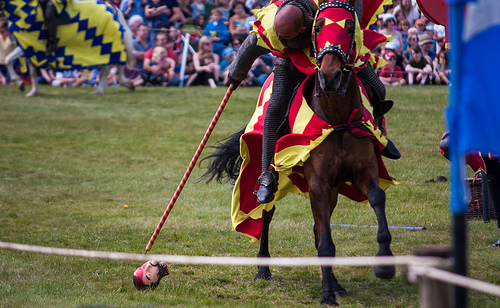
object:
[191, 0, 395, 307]
horse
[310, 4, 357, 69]
mask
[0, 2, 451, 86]
people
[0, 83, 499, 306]
grass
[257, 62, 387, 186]
legging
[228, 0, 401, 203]
man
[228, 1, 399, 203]
armor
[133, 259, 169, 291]
head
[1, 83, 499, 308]
ground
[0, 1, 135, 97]
horse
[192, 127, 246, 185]
tail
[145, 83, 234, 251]
pole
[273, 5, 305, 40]
head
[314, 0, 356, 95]
head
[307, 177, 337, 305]
legs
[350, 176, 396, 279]
leg